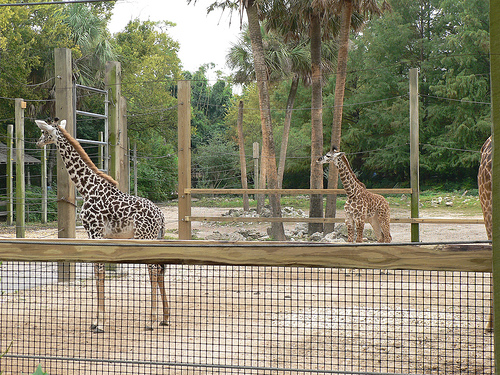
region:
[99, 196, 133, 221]
pattern on side of giraffe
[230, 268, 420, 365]
black metal fencing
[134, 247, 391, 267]
brown wooden fence post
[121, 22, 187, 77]
tree covered in green leaves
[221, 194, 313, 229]
pile of grey rocks at base of tree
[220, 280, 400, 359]
ground covered in dirt behind fence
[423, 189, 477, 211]
grass growing on ground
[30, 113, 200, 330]
giraffe standing in dirt field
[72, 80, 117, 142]
silver metal fencing gate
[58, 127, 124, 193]
black and orange fur on giraffe neck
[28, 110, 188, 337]
the giraffe on the left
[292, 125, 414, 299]
the giraffe on the right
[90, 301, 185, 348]
these are giraffe hooves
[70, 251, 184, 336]
these are giraffe legs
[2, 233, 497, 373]
this is a fence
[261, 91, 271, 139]
this is tree bark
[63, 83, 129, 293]
this is a ladder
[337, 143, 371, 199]
this is a mane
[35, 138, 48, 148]
this is a nose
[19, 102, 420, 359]
these are brown giraffes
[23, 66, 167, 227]
door to the giraffe exhibit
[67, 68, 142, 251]
door is made of metal poles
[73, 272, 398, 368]
fence has netting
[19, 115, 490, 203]
three giraffes in the photo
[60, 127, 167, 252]
giraffes are brown and white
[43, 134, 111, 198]
giraffe has a long neck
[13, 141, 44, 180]
roof on the other side of exhibit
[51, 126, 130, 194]
giraffe has hair down it's neck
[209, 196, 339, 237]
rocks around the trees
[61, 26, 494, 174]
trees along the back of exhibit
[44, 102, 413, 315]
two giraffes in enclosure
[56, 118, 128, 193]
giraffe has long brown mane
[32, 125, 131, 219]
giraffe has brown and white spots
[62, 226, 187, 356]
giraffe has white legs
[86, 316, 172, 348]
giraffe has dark brown feet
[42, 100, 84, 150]
giraffe has white ears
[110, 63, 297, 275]
wooden poles in enclosure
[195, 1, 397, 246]
palm tree next to giraffe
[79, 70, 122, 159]
metal bars on poles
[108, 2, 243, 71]
sky is hazy and grey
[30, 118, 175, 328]
the giraffe is looking left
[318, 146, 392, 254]
the giraffe is looking left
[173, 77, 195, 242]
a wooden post is erected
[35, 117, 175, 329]
the giraffe is brown and white in color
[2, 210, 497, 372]
the ground is made of dirt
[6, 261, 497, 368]
the fence is made of wire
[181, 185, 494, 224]
two wooden beams are across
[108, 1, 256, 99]
the sky is overcast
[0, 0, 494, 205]
dense vegetation is on the background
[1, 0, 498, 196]
the trees are filled with green leaves